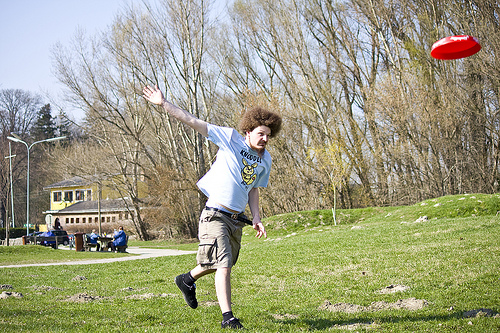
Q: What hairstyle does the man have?
A: Afro.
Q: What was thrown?
A: Frisbee.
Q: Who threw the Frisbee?
A: Man with Afro.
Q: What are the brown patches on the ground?
A: Dirt.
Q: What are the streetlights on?
A: Poles.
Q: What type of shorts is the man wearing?
A: Cargo.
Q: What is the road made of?
A: Cement.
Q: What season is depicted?
A: Autumn.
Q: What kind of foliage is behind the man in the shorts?
A: Trees.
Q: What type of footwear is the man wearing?
A: Sneakers.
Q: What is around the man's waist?
A: Belt.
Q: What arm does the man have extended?
A: Right.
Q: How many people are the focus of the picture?
A: One.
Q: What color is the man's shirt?
A: Blue.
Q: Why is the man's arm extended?
A: He just threw a frisbee.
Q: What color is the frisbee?
A: Red.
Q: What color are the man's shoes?
A: Black.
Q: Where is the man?
A: Field or Park.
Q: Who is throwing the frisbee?
A: A man.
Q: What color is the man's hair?
A: Brown.